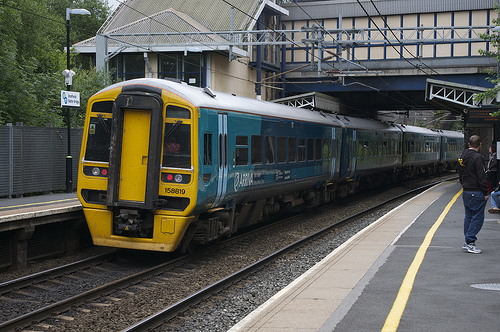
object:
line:
[378, 187, 461, 332]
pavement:
[227, 180, 499, 332]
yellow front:
[76, 83, 198, 252]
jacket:
[457, 148, 489, 191]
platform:
[228, 166, 499, 330]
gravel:
[133, 274, 206, 330]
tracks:
[258, 225, 322, 259]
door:
[106, 92, 164, 210]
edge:
[191, 143, 195, 175]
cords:
[46, 0, 233, 69]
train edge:
[191, 106, 199, 205]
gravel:
[242, 232, 288, 295]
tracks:
[46, 262, 105, 303]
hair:
[469, 135, 481, 148]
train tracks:
[0, 303, 120, 331]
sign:
[60, 89, 80, 107]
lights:
[174, 174, 183, 182]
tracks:
[180, 261, 233, 327]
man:
[458, 134, 490, 253]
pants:
[461, 191, 487, 245]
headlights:
[92, 167, 107, 175]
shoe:
[461, 242, 482, 254]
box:
[62, 69, 76, 86]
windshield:
[84, 112, 113, 162]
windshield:
[161, 120, 191, 170]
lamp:
[64, 8, 91, 194]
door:
[208, 113, 228, 209]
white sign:
[189, 78, 196, 84]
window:
[182, 51, 208, 88]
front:
[76, 76, 465, 254]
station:
[0, 77, 497, 332]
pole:
[64, 10, 74, 193]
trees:
[3, 0, 56, 120]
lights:
[166, 174, 173, 181]